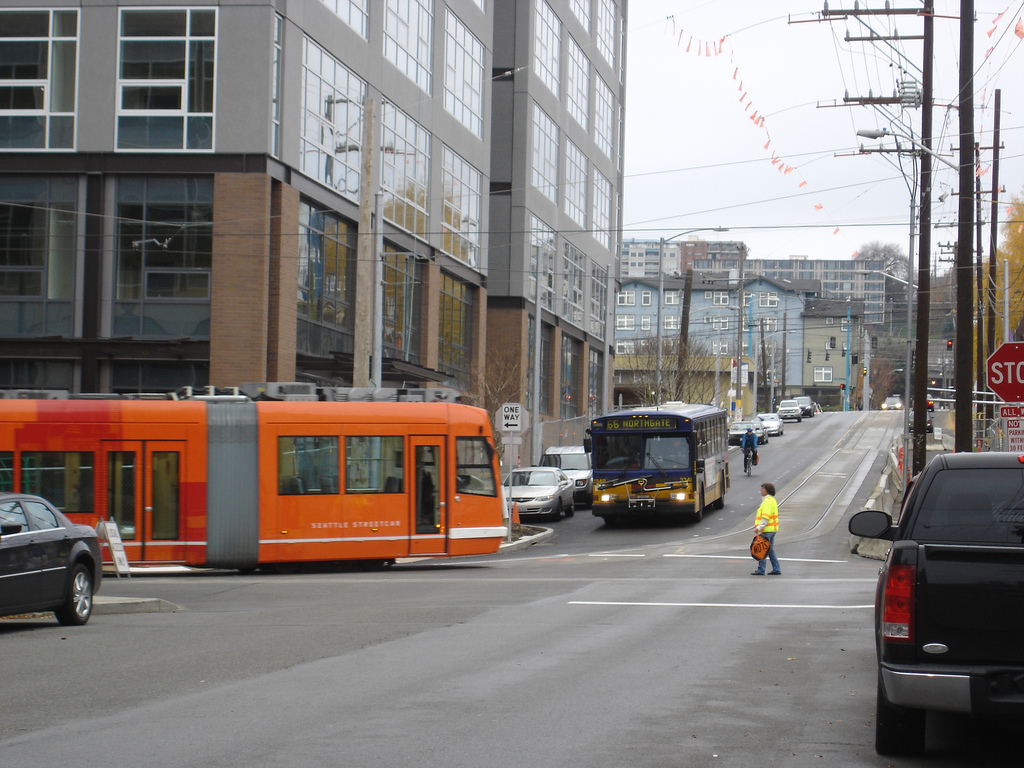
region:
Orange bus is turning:
[0, 385, 509, 576]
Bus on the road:
[5, 391, 1012, 765]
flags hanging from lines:
[643, 3, 1018, 251]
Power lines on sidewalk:
[791, 4, 1020, 546]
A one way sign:
[501, 398, 522, 550]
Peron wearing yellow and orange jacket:
[747, 476, 779, 576]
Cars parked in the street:
[4, 397, 1017, 767]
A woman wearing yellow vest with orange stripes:
[751, 476, 783, 533]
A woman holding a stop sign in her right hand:
[746, 481, 785, 564]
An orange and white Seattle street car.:
[5, 375, 511, 565]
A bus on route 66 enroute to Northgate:
[594, 410, 681, 437]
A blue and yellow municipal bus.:
[582, 397, 731, 522]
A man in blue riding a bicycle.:
[739, 427, 762, 473]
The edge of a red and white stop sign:
[985, 337, 1023, 398]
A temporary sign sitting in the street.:
[88, 512, 136, 589]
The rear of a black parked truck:
[846, 446, 1023, 757]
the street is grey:
[458, 627, 675, 725]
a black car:
[9, 495, 118, 620]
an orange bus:
[264, 396, 512, 561]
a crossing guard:
[739, 471, 813, 577]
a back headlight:
[875, 570, 920, 640]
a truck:
[873, 457, 1023, 705]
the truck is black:
[840, 444, 1023, 692]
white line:
[623, 593, 713, 626]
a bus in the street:
[591, 409, 713, 508]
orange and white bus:
[35, 355, 497, 586]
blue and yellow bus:
[573, 393, 748, 539]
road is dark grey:
[497, 622, 719, 733]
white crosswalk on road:
[623, 531, 783, 627]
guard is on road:
[740, 481, 807, 589]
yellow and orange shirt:
[734, 487, 798, 571]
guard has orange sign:
[740, 528, 783, 589]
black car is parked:
[5, 508, 122, 636]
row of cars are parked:
[500, 426, 578, 545]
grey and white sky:
[646, 89, 757, 255]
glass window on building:
[121, 36, 183, 76]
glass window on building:
[118, 80, 186, 113]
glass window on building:
[115, 115, 182, 148]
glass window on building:
[117, 8, 179, 31]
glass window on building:
[188, 5, 208, 31]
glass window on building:
[184, 36, 211, 112]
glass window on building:
[182, 115, 211, 147]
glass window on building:
[43, 36, 70, 117]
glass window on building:
[49, 12, 78, 39]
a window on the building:
[293, 210, 354, 338]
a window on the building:
[146, 213, 195, 305]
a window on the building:
[116, 91, 171, 153]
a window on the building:
[301, 134, 328, 201]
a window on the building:
[398, 135, 431, 224]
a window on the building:
[448, 169, 488, 255]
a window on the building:
[531, 239, 545, 287]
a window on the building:
[532, 223, 562, 306]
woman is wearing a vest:
[754, 490, 794, 535]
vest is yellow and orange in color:
[743, 495, 788, 534]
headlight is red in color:
[869, 562, 940, 660]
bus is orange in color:
[8, 350, 559, 579]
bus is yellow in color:
[571, 369, 730, 537]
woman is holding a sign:
[743, 519, 781, 576]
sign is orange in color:
[733, 540, 781, 567]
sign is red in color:
[988, 320, 1021, 396]